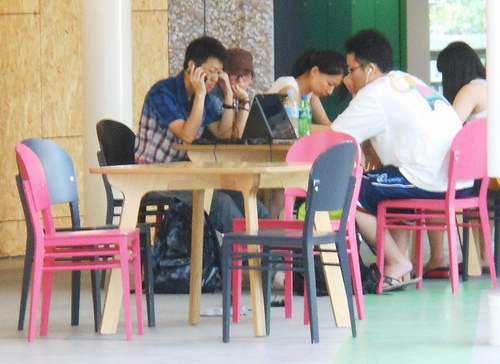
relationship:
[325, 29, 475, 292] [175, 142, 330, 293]
person sitting at table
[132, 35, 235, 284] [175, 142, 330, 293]
person sitting at table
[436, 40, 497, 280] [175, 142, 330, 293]
person sitting at table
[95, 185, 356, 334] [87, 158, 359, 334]
legs are beneath table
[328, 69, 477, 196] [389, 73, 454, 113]
shirt has a design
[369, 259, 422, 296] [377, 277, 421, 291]
foot wearing a flip flop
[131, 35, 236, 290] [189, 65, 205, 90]
man has a hand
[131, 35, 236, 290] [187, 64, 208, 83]
man using phone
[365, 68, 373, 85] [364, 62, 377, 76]
earbuds are in ear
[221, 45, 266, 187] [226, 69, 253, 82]
girl wearing glasses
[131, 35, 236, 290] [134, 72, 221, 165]
man wearing a shirt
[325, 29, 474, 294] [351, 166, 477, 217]
man wearing shorts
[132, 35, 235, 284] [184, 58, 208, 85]
person talking on a cell phone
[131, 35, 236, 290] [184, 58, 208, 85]
man talking on a cell phone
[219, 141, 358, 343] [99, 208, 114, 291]
chair has a leg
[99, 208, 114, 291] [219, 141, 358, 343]
leg attached to a chair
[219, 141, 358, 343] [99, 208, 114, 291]
chair has a metal leg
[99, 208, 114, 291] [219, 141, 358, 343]
leg connected to a chair